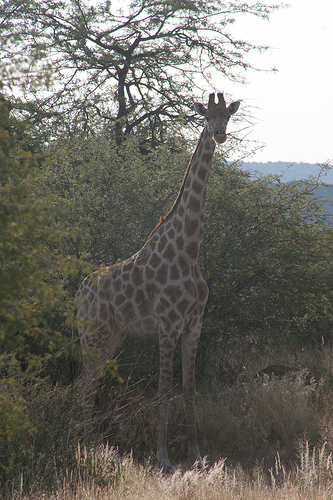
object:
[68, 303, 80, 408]
tail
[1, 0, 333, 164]
clouds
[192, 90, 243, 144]
head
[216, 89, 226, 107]
horn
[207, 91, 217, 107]
horn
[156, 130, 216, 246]
neck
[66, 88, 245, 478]
giraffe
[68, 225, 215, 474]
body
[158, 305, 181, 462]
legs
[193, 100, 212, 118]
ear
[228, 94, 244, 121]
ear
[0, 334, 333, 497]
land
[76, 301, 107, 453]
legs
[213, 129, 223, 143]
giraffe nostrils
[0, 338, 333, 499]
yard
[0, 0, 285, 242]
trees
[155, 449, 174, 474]
feet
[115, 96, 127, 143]
woods